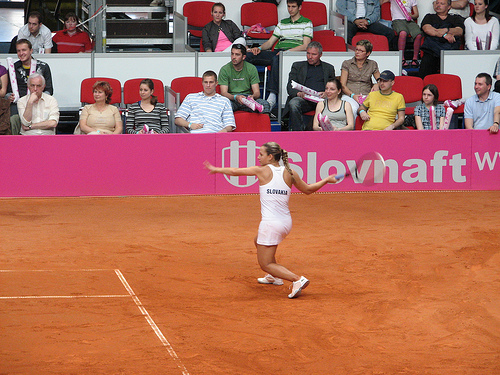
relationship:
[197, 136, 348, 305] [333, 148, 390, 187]
woman swinging racket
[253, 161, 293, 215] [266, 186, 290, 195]
shirt print slovakia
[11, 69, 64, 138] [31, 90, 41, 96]
man hand on lip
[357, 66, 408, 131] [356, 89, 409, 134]
man wearing yellow shirt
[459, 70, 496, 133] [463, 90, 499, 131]
man wearing blue polo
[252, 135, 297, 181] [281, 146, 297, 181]
hair in a braid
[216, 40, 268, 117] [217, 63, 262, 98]
man wearing green shirt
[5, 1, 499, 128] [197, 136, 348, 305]
spectators watching woman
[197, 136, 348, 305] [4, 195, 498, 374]
woman on court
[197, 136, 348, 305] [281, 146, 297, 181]
woman combs in a ponytail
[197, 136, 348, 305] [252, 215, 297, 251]
woman wearing white shorts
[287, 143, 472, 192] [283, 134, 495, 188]
logo on tennis wall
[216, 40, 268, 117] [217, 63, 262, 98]
man wearing green t-shirt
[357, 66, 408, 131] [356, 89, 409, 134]
man wearing yellow t-shirt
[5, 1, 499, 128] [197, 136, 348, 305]
spectators at tennis match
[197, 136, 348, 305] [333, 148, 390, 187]
woman swinging tennis racquet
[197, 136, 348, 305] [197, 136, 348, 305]
woman playing woman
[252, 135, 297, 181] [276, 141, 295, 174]
hair in a pony tail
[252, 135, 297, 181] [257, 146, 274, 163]
head view of side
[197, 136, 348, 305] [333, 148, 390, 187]
girl swinging racket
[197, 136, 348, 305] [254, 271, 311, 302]
woman worn white shoes